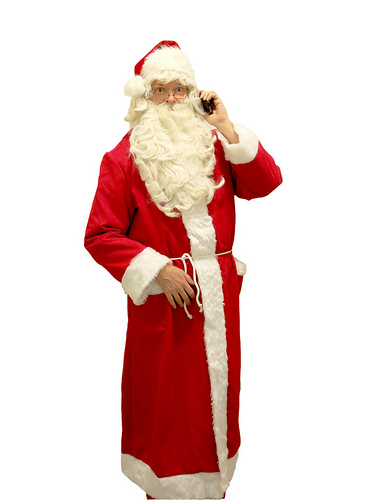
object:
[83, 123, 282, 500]
robe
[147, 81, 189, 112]
spectacle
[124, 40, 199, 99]
fur hat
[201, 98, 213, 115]
cell phone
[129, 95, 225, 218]
beard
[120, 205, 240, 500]
faux fur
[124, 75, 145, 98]
ball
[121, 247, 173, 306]
fur trim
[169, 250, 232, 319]
rope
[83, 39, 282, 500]
costume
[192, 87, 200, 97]
ear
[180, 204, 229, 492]
trim